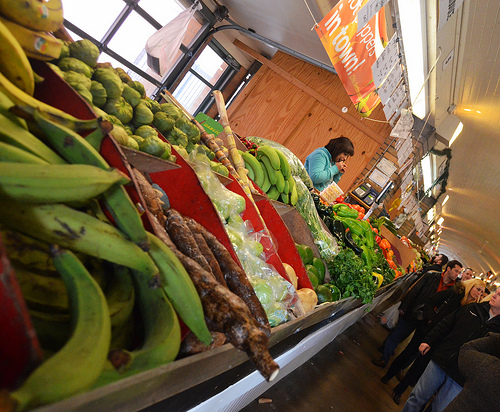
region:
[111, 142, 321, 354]
red color on inside of stalls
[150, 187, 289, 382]
yucca plant in the stall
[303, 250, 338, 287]
shiny green skin on avocado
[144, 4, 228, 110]
white plastic bag on hook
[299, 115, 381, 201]
woman standing behind the stall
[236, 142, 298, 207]
green bunch of bananas for sale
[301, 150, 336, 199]
woman wearing turquoise sweater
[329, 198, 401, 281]
green peppers and orange peppers for sale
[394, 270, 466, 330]
man in black jacket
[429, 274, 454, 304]
man wearing orange shirt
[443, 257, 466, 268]
man with short hair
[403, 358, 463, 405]
man in blue jeans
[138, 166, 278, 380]
Brown tubers in a box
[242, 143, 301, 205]
Unripe bananas in a box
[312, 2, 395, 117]
An orange banner with white letters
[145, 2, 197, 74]
A plastic bag hanging over a window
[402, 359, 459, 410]
Blue jeans on a person's leg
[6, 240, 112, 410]
A big green plantane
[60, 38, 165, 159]
A bunch of green squash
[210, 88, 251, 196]
A couple of pieces of sugar cane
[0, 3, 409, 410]
A bunch of fruit and vegetables being sold at a farmers market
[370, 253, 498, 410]
People walking around at a farmers market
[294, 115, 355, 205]
woman wearing teal sweatshirt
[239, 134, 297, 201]
bananas in a bin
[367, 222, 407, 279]
bell peppers in a bin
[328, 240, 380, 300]
leafy greens in a bin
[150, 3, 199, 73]
plastic bag hanging from ceiling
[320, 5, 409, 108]
sign hanging from ceiling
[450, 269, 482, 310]
woman with blonde hair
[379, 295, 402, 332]
plastic bag on the floor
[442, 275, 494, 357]
man standing in line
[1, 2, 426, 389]
display of fruit in a market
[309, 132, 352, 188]
woman wearing blue shirt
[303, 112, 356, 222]
woman standing behind food display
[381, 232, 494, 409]
a group of people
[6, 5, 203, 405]
a bunch of bananas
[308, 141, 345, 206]
a woman wearing a blue top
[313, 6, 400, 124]
an orange and white banner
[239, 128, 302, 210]
pile of green bananas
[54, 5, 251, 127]
windows in the background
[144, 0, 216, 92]
bag hanging from the window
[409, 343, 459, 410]
a pair of jeans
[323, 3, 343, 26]
white letter on sign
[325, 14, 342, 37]
white letter on sign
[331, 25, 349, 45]
white letter on sign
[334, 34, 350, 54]
white letter on sign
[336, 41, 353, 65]
white letter on sign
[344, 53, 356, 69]
white letter on sign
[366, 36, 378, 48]
white letter on sign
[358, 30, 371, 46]
white letter on sign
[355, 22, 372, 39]
white letter on sign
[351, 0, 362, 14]
white letter on sign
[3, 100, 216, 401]
plantains at a market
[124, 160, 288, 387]
gingers roots on display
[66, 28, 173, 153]
round green fruits on display